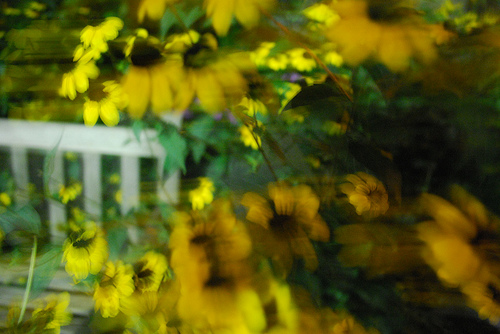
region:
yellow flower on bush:
[120, 35, 175, 117]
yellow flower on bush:
[185, 230, 257, 325]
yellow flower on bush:
[60, 232, 118, 283]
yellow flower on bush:
[36, 302, 70, 327]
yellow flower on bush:
[80, 86, 122, 128]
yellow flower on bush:
[331, 10, 421, 76]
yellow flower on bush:
[430, 212, 487, 289]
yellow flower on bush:
[263, 191, 314, 258]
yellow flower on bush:
[295, 301, 356, 331]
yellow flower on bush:
[261, 200, 310, 256]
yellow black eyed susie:
[125, 39, 182, 107]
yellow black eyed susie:
[69, 232, 119, 279]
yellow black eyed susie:
[134, 255, 168, 297]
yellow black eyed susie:
[191, 260, 253, 320]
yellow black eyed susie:
[429, 202, 484, 287]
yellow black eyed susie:
[345, 170, 384, 218]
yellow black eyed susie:
[259, 195, 326, 264]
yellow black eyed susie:
[328, 2, 421, 59]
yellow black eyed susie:
[88, 85, 125, 122]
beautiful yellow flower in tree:
[48, 13, 326, 157]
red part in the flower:
[267, 210, 294, 236]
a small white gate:
[11, 128, 218, 251]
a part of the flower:
[178, 176, 220, 226]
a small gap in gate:
[63, 160, 94, 284]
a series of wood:
[11, 147, 188, 242]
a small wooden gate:
[16, 115, 253, 267]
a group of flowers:
[47, 22, 426, 330]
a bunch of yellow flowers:
[42, 16, 451, 332]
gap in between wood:
[18, 155, 185, 233]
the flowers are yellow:
[160, 97, 270, 290]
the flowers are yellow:
[73, 207, 176, 288]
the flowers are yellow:
[228, 255, 277, 317]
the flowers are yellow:
[179, 245, 246, 320]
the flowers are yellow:
[147, 229, 217, 316]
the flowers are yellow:
[159, 188, 260, 331]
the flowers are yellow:
[190, 228, 275, 323]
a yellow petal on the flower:
[81, 25, 96, 49]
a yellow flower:
[75, 71, 134, 131]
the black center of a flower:
[70, 232, 97, 249]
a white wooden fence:
[0, 115, 210, 282]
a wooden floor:
[0, 255, 127, 328]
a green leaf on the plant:
[158, 127, 194, 177]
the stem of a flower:
[261, 6, 361, 108]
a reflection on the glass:
[1, 0, 331, 170]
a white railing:
[1, 117, 173, 168]